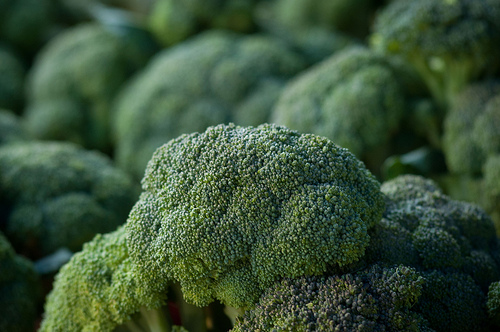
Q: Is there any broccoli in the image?
A: Yes, there is broccoli.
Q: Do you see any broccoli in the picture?
A: Yes, there is broccoli.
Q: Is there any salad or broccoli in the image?
A: Yes, there is broccoli.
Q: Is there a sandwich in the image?
A: No, there are no sandwiches.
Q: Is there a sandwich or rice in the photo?
A: No, there are no sandwiches or rice.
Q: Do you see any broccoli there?
A: Yes, there is broccoli.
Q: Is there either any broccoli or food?
A: Yes, there is broccoli.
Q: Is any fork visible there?
A: No, there are no forks.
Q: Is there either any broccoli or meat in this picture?
A: Yes, there is broccoli.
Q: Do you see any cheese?
A: No, there is no cheese.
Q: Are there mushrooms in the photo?
A: No, there are no mushrooms.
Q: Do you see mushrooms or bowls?
A: No, there are no mushrooms or bowls.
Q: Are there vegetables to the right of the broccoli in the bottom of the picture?
A: Yes, there is a vegetable to the right of the broccoli.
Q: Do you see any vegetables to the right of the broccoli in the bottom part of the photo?
A: Yes, there is a vegetable to the right of the broccoli.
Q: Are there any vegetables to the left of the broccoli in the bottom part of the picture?
A: No, the vegetable is to the right of the broccoli.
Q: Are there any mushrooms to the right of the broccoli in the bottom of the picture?
A: No, there is a vegetable to the right of the broccoli.